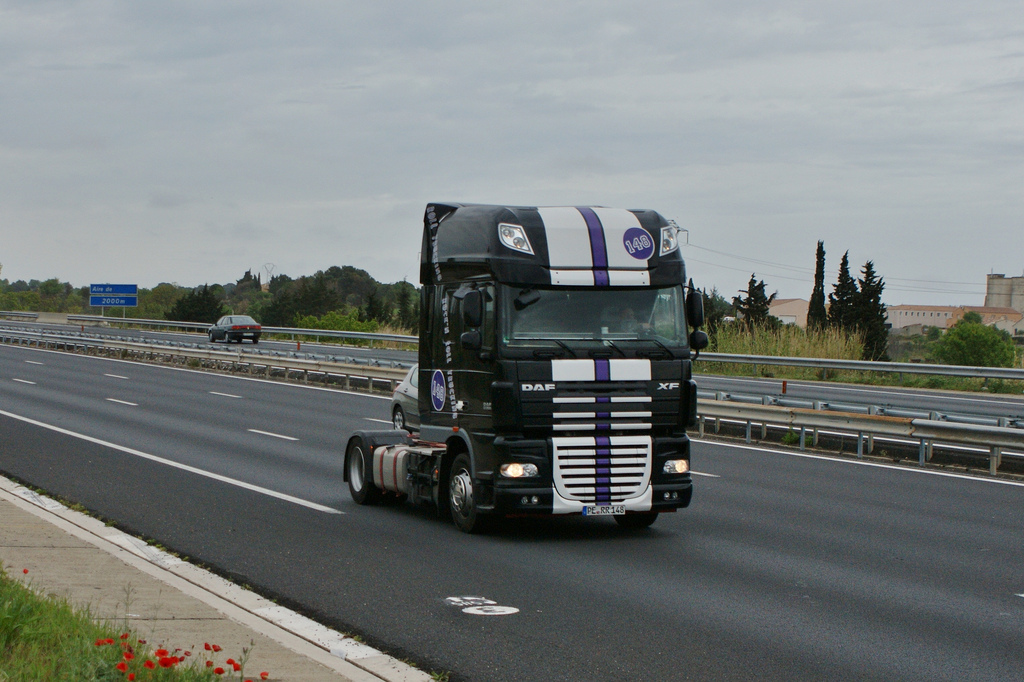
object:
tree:
[276, 265, 423, 336]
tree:
[731, 272, 783, 331]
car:
[206, 315, 261, 343]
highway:
[0, 313, 1024, 682]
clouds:
[0, 0, 1024, 307]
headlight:
[499, 463, 538, 477]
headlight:
[663, 460, 688, 474]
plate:
[581, 505, 624, 515]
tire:
[347, 439, 382, 505]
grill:
[551, 359, 653, 515]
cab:
[493, 285, 690, 359]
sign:
[88, 283, 138, 308]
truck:
[340, 201, 709, 536]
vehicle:
[391, 363, 423, 434]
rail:
[0, 321, 1024, 482]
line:
[0, 408, 343, 515]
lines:
[249, 429, 301, 441]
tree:
[807, 240, 827, 342]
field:
[692, 321, 1024, 395]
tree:
[843, 258, 893, 361]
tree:
[162, 282, 230, 334]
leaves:
[881, 281, 887, 287]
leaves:
[739, 290, 748, 294]